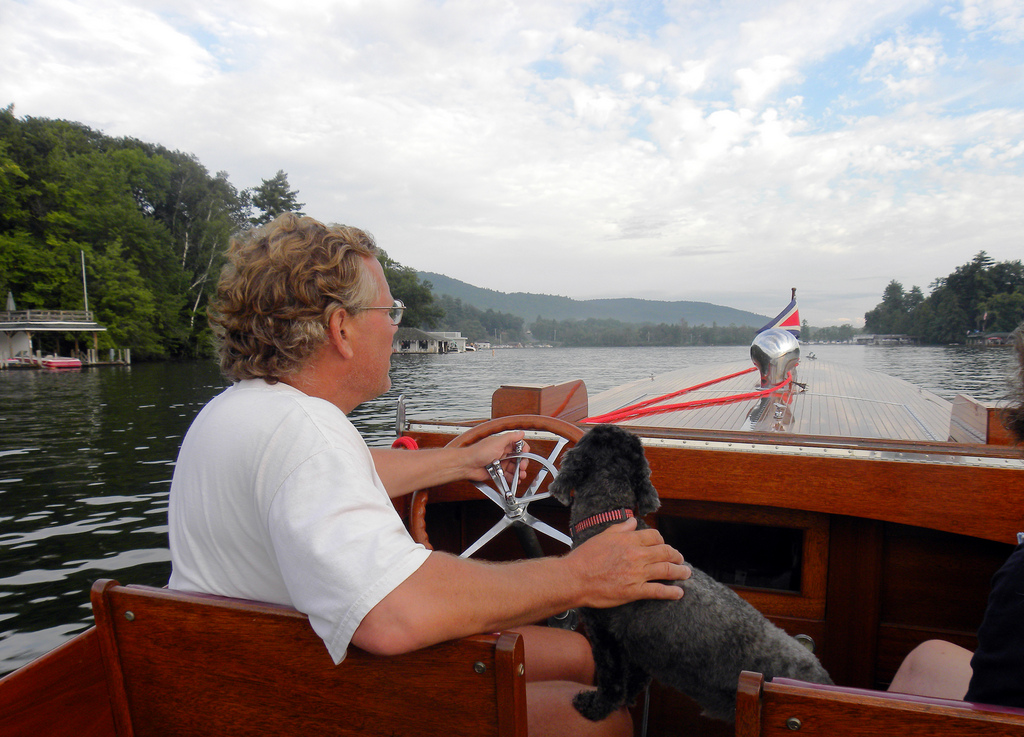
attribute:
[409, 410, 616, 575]
wheel — steering, wood, white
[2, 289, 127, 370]
house — boat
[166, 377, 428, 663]
shirt — white